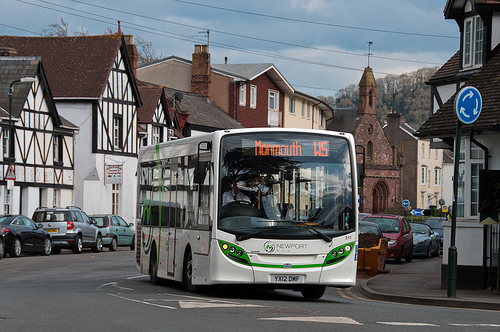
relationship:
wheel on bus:
[182, 251, 194, 297] [134, 125, 361, 297]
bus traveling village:
[127, 120, 376, 303] [2, 1, 497, 326]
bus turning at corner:
[134, 125, 361, 297] [360, 270, 444, 303]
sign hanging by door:
[102, 161, 125, 186] [109, 182, 120, 212]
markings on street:
[449, 321, 500, 325] [2, 243, 498, 329]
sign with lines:
[456, 82, 484, 122] [458, 89, 480, 117]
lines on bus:
[211, 233, 371, 280] [127, 120, 376, 303]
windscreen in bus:
[214, 122, 380, 259] [127, 120, 376, 303]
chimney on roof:
[123, 32, 138, 77] [1, 55, 38, 137]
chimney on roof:
[189, 42, 210, 98] [135, 62, 337, 116]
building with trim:
[0, 47, 76, 208] [90, 44, 140, 157]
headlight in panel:
[221, 241, 254, 266] [218, 238, 254, 264]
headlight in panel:
[319, 231, 356, 268] [321, 239, 357, 269]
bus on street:
[127, 120, 376, 303] [2, 243, 498, 329]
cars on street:
[1, 203, 138, 259] [6, 220, 498, 327]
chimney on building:
[189, 42, 210, 98] [0, 47, 76, 208]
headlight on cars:
[222, 243, 229, 250] [1, 213, 52, 258]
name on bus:
[261, 237, 318, 258] [136, 121, 360, 296]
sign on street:
[452, 87, 481, 125] [2, 243, 498, 329]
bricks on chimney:
[192, 74, 210, 96] [189, 42, 210, 98]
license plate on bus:
[273, 274, 302, 282] [136, 121, 360, 296]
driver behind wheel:
[222, 179, 260, 204] [216, 180, 264, 247]